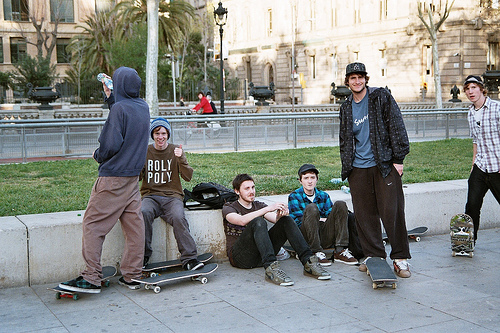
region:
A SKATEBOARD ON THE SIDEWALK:
[361, 246, 408, 294]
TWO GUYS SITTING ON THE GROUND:
[218, 171, 364, 287]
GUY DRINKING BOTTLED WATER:
[55, 61, 155, 303]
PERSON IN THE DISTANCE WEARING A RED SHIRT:
[186, 88, 231, 118]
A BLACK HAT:
[339, 62, 379, 81]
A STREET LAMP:
[208, 0, 235, 115]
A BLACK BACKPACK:
[181, 182, 241, 215]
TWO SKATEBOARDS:
[126, 246, 224, 297]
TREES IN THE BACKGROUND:
[69, 1, 201, 107]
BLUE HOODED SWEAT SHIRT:
[87, 58, 162, 184]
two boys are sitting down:
[214, 160, 362, 287]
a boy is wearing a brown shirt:
[139, 120, 200, 275]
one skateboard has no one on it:
[129, 259, 219, 291]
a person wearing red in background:
[189, 89, 213, 133]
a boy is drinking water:
[77, 66, 150, 293]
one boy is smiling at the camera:
[336, 60, 413, 277]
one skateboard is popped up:
[451, 211, 474, 257]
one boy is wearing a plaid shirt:
[459, 75, 498, 248]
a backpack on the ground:
[182, 182, 241, 208]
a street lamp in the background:
[213, 2, 229, 113]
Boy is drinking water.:
[31, 50, 151, 294]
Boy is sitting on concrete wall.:
[129, 112, 219, 276]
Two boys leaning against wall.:
[221, 158, 360, 285]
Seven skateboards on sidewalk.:
[47, 210, 494, 303]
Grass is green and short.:
[3, 127, 498, 239]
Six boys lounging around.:
[53, 34, 499, 308]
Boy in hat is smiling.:
[335, 57, 413, 281]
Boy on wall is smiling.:
[123, 107, 206, 279]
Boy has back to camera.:
[54, 47, 155, 294]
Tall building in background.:
[0, 0, 499, 109]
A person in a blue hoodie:
[84, 62, 146, 178]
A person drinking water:
[88, 61, 145, 102]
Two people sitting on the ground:
[225, 168, 355, 282]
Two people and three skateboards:
[75, 53, 220, 292]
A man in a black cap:
[288, 154, 325, 197]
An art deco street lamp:
[206, 2, 233, 99]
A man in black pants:
[335, 58, 424, 251]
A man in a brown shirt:
[141, 121, 191, 197]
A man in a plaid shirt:
[444, 70, 497, 173]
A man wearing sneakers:
[223, 168, 330, 288]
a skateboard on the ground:
[362, 251, 399, 298]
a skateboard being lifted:
[446, 208, 481, 263]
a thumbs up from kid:
[172, 142, 186, 157]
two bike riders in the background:
[175, 85, 226, 140]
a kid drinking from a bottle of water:
[44, 62, 157, 307]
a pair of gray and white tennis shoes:
[257, 251, 336, 288]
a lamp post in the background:
[210, 0, 235, 130]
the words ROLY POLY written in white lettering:
[145, 156, 175, 187]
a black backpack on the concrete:
[180, 176, 242, 216]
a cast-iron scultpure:
[24, 80, 68, 110]